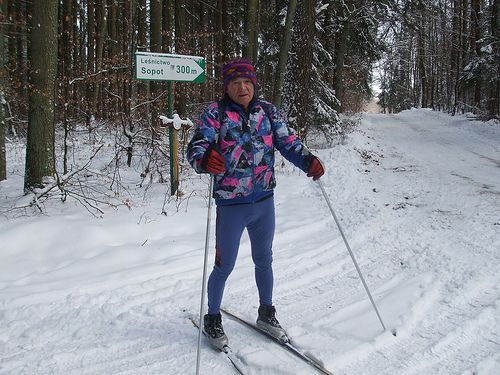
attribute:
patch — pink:
[47, 107, 144, 198]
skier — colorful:
[208, 55, 281, 157]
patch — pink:
[217, 135, 242, 156]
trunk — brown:
[23, 14, 68, 204]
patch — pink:
[263, 130, 284, 150]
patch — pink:
[261, 132, 275, 145]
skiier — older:
[224, 70, 304, 345]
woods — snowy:
[292, 15, 485, 160]